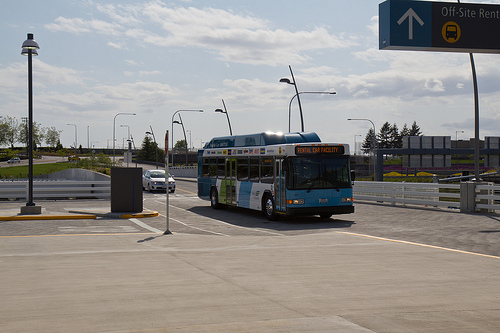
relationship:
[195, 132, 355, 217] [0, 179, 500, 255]
bus on roadway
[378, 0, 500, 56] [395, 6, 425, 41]
sign with arrow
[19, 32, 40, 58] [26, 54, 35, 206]
street light on pole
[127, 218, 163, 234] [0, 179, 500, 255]
lines on roadway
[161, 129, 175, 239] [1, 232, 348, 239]
sign on curb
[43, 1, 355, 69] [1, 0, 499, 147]
clouds are in sky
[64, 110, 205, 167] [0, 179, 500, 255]
lights next to roadway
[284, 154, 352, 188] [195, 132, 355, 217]
window of bus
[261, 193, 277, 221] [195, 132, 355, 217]
wheel of bus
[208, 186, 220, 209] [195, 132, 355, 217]
tire of bus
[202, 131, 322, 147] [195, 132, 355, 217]
top of bus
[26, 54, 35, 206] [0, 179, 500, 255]
pole next to street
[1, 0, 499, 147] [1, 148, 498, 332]
sky above land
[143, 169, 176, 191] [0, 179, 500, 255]
car on roadway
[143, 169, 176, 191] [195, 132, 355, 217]
car behind bus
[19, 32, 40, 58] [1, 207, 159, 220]
street light on median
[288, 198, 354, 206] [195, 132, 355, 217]
headlights of bus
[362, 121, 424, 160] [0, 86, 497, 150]
trees in distance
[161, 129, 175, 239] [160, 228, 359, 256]
stop sign at corner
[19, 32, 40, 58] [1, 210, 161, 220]
street light on sidewalk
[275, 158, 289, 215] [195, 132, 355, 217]
doors of bus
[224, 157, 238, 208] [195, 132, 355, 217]
doors of bus